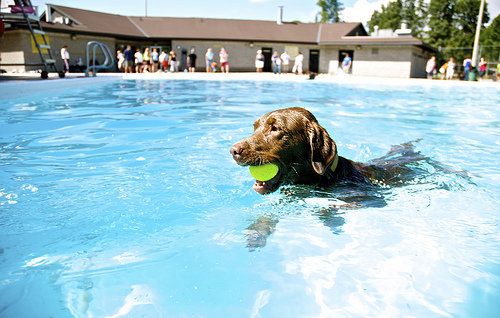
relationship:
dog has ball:
[216, 99, 467, 246] [244, 157, 285, 185]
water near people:
[3, 71, 499, 313] [114, 41, 313, 78]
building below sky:
[29, 0, 494, 28] [4, 4, 430, 80]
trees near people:
[317, 0, 499, 62] [114, 41, 313, 78]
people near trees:
[114, 41, 313, 78] [317, 0, 499, 62]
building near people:
[29, 0, 494, 28] [114, 41, 313, 78]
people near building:
[114, 41, 313, 78] [29, 0, 494, 28]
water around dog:
[3, 71, 499, 313] [216, 99, 467, 246]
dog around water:
[216, 99, 467, 246] [3, 71, 499, 313]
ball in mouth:
[245, 159, 275, 180] [232, 141, 282, 196]